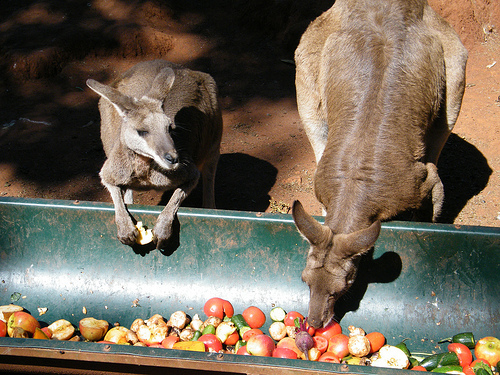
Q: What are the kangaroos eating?
A: Apples and veggies.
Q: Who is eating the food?
A: Kangaroos.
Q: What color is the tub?
A: Green.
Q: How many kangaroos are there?
A: Two.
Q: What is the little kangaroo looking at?
A: The bigger kangaroo.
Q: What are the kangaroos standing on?
A: Dirt.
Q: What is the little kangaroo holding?
A: An apple.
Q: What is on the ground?
A: Shadows.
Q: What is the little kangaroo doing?
A: Looking at someone.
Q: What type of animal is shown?
A: Kangaroos.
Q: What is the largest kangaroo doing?
A: Eating.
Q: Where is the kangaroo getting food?
A: Metal trough.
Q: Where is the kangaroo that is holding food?
A: Kangaroo on the left.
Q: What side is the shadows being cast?
A: On the right.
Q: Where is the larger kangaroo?
A: Kangaroo on the right.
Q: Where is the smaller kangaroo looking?
A: To the right.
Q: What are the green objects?
A: Peppers.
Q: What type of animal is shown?
A: Kangaroo.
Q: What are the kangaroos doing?
A: Eating.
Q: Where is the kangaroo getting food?
A: Trough.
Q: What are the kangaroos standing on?
A: Dirt.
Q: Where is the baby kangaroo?
A: Left side of the image.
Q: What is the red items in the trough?
A: Tomatoes.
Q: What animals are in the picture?
A: Kangaroos.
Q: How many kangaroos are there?
A: Two.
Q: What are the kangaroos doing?
A: Eating.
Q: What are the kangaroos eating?
A: Vegetables.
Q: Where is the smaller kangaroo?
A: On the left.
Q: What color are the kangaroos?
A: Brown.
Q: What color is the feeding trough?
A: Green.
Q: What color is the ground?
A: Brown.